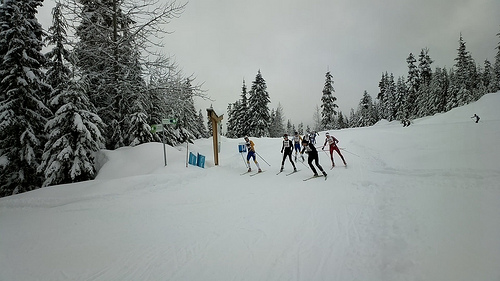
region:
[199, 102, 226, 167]
a wooden sign in snow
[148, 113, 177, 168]
direction sign on pole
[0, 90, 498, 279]
ground covered in snow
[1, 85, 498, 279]
snow is thick and white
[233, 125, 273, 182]
skier in a yellow suit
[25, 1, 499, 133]
sky is gray and overcast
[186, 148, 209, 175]
blue signs in snow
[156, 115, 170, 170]
pole is silver and metal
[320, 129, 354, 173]
skier in a red suit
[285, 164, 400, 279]
ski tracks in snow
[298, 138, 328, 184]
a cross country skier dressed in black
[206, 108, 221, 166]
a wooden trail marker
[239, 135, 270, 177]
cross country skier with a yellow ski jacket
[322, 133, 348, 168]
cross country skier dressed in red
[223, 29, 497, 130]
large pine trees covered in snow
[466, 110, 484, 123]
a skier up the hill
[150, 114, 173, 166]
trail markers and pole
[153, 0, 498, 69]
grey foggy sky in the distance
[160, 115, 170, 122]
green trail marker sign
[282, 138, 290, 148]
racing identification number tag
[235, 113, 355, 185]
a group of cross country skiers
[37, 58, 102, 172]
evergreen trees with snow on them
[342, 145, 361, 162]
a cross country ski pole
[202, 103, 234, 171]
a sign on a ski trail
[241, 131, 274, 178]
a skier in yellow and black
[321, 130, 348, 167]
a skier in red and white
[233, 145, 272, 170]
a skier holding poles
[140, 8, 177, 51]
a tree branch without leaves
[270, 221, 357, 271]
ski tracks on a trail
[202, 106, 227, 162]
a wooden sign post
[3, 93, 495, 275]
a snowy hillside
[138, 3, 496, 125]
cloudy sky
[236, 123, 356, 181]
a group of skiers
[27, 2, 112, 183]
a snow covered pine tree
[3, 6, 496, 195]
snow covered pine trees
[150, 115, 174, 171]
a ski slope trail market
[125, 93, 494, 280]
a ski slope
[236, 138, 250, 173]
a flag marker on the ski slope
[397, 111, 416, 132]
a pair of skiers behind the main group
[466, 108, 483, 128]
a single skier away from the group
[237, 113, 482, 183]
people skiing in competition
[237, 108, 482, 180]
quickly racing against eachother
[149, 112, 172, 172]
sign placed in ground surrounded by snow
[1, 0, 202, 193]
trees branches are heavy with snow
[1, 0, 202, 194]
frozen forest on boundaries of race way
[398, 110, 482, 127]
racers are far behind others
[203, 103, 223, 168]
tall wooden sign with informative information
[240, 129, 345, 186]
soaring at deadly speeds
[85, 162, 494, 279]
ski tracks leading through snow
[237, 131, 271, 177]
leaning to one side to turn